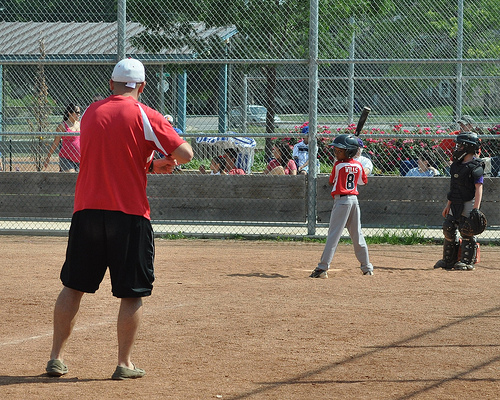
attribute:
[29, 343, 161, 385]
shoes — black and white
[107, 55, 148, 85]
hat — white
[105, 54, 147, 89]
hat — white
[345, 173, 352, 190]
number — black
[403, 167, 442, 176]
shirt — red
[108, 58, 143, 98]
hat — white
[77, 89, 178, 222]
shirt — red and white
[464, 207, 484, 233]
mitt — black, baseball mitt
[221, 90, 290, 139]
car — silver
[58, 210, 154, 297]
shorts — black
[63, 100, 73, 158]
shirt — red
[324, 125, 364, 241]
helmet — black